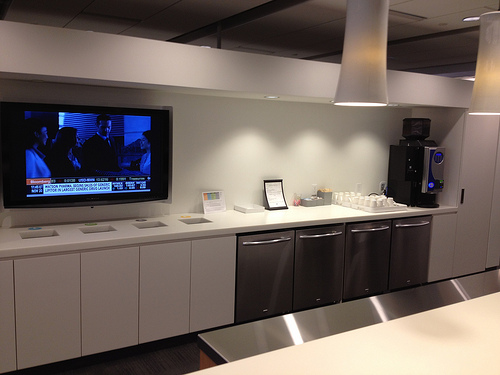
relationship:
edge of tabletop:
[185, 312, 256, 367] [251, 266, 498, 372]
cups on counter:
[331, 188, 406, 211] [3, 187, 455, 257]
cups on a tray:
[388, 198, 393, 204] [330, 195, 407, 212]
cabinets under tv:
[5, 233, 235, 363] [3, 102, 172, 206]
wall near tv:
[182, 118, 242, 163] [5, 102, 176, 216]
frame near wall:
[261, 178, 286, 211] [202, 100, 406, 203]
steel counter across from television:
[194, 265, 498, 360] [4, 103, 173, 203]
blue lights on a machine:
[433, 150, 445, 164] [388, 114, 445, 209]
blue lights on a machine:
[427, 179, 435, 190] [388, 114, 445, 209]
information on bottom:
[22, 177, 152, 200] [5, 170, 170, 204]